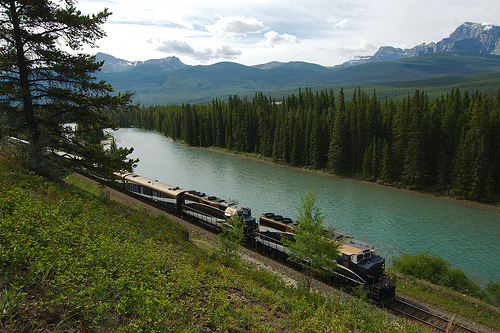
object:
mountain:
[0, 52, 266, 107]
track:
[389, 298, 479, 332]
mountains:
[330, 22, 498, 70]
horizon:
[0, 0, 500, 91]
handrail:
[366, 274, 397, 306]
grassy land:
[0, 158, 427, 333]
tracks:
[254, 246, 287, 264]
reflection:
[237, 183, 289, 202]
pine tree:
[303, 107, 313, 169]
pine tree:
[250, 92, 260, 156]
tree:
[0, 0, 141, 182]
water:
[442, 241, 462, 253]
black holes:
[281, 218, 293, 224]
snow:
[477, 20, 496, 32]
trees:
[449, 82, 498, 199]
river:
[61, 121, 500, 294]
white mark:
[254, 236, 283, 252]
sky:
[118, 3, 153, 22]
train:
[5, 135, 398, 306]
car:
[246, 212, 397, 305]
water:
[182, 144, 203, 161]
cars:
[181, 190, 260, 247]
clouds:
[139, 2, 291, 52]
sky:
[420, 1, 447, 24]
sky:
[300, 38, 347, 53]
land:
[443, 57, 496, 87]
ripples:
[292, 176, 336, 197]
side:
[258, 217, 361, 296]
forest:
[76, 85, 500, 204]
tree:
[395, 87, 434, 194]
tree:
[352, 86, 385, 180]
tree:
[167, 111, 182, 142]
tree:
[137, 104, 151, 132]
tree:
[296, 82, 323, 175]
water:
[346, 223, 371, 235]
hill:
[0, 136, 500, 332]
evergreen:
[120, 115, 130, 128]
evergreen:
[182, 102, 195, 146]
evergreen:
[309, 110, 323, 169]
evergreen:
[256, 97, 271, 159]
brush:
[390, 251, 500, 326]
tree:
[277, 185, 349, 292]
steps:
[364, 273, 398, 306]